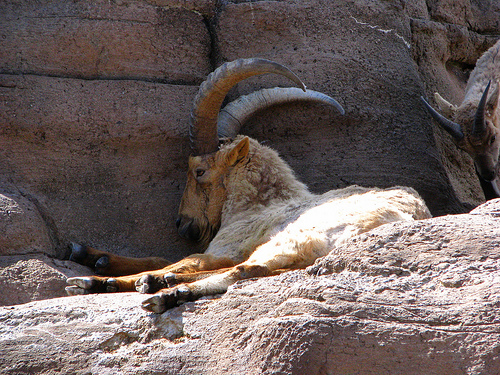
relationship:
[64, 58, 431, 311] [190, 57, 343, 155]
animal has horns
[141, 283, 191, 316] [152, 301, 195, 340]
rear foot casts shadow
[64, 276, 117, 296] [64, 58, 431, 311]
hoof on animal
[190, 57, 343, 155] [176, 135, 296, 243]
horns on head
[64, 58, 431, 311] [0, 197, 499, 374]
animal on cliff face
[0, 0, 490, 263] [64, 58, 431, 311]
wall behind animal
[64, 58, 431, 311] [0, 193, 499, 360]
animal in light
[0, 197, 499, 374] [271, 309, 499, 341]
cliff face has grooves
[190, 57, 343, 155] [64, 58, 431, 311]
horns on animal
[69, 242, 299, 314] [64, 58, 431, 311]
legs on animal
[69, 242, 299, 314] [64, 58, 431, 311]
legs are on animal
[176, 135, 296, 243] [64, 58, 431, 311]
head on animal